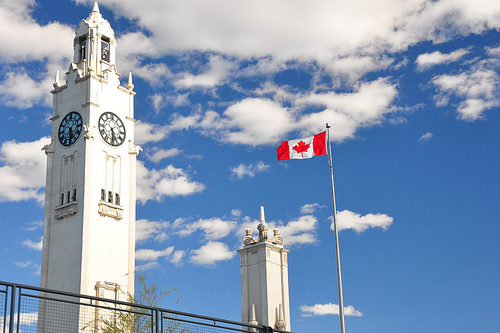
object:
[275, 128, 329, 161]
flag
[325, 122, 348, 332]
pole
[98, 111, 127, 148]
clock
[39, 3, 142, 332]
building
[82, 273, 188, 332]
tree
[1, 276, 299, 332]
fence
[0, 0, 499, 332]
sky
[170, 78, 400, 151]
clouds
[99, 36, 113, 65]
window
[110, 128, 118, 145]
5:30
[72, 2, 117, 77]
spire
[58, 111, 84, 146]
clock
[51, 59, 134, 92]
parapets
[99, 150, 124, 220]
windows